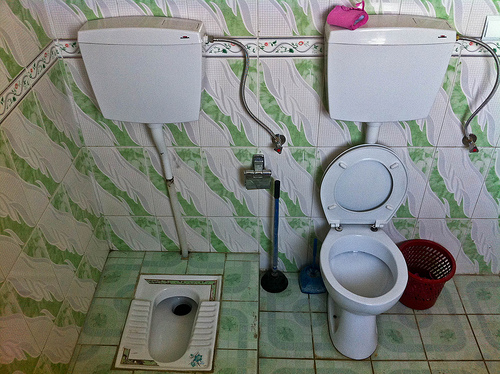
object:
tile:
[256, 309, 316, 361]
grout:
[309, 313, 316, 358]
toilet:
[317, 143, 411, 363]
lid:
[319, 143, 409, 231]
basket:
[393, 239, 456, 311]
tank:
[327, 15, 456, 125]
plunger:
[259, 178, 289, 292]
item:
[324, 3, 370, 31]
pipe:
[211, 37, 278, 141]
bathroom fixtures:
[75, 16, 201, 125]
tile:
[81, 146, 154, 223]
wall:
[49, 1, 498, 275]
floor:
[68, 249, 498, 373]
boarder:
[58, 37, 500, 57]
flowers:
[288, 48, 294, 54]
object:
[245, 154, 273, 189]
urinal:
[114, 271, 226, 372]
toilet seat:
[320, 146, 406, 233]